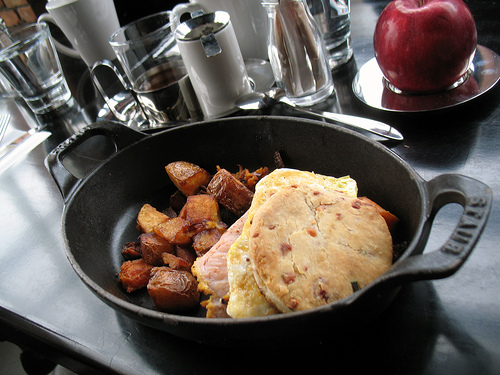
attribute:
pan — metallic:
[42, 109, 484, 339]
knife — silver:
[282, 96, 405, 148]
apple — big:
[365, 0, 497, 96]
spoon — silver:
[233, 88, 404, 144]